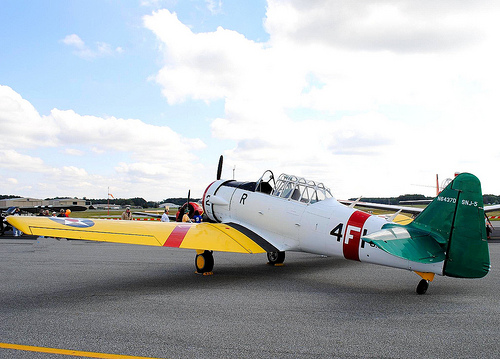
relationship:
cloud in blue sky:
[0, 0, 496, 194] [0, 2, 212, 140]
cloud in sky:
[0, 0, 496, 194] [2, 2, 481, 173]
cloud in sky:
[0, 0, 496, 194] [0, 0, 499, 207]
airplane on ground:
[4, 154, 491, 295] [0, 233, 498, 356]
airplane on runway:
[4, 154, 491, 295] [0, 233, 500, 355]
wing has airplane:
[4, 214, 276, 254] [4, 154, 491, 295]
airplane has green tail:
[4, 154, 491, 295] [341, 164, 492, 308]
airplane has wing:
[4, 154, 491, 295] [4, 214, 275, 256]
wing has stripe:
[4, 214, 275, 256] [160, 217, 199, 247]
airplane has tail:
[4, 154, 491, 295] [359, 170, 494, 287]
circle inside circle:
[50, 215, 98, 229] [49, 209, 95, 227]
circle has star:
[50, 215, 98, 229] [53, 216, 90, 227]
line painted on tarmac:
[0, 342, 154, 357] [0, 232, 499, 355]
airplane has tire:
[4, 154, 491, 295] [196, 242, 217, 277]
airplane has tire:
[4, 154, 491, 295] [412, 276, 430, 293]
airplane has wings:
[4, 154, 491, 295] [2, 214, 297, 260]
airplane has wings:
[4, 154, 491, 295] [355, 227, 447, 264]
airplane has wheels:
[4, 154, 491, 295] [195, 249, 284, 271]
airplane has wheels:
[4, 154, 491, 295] [402, 270, 444, 302]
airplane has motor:
[4, 154, 491, 295] [155, 157, 236, 218]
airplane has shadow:
[4, 154, 491, 295] [43, 270, 207, 300]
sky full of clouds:
[0, 0, 499, 207] [114, 35, 389, 108]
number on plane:
[332, 221, 344, 245] [44, 80, 497, 326]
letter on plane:
[342, 221, 362, 250] [44, 80, 497, 326]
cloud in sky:
[151, 0, 497, 112] [0, 0, 499, 207]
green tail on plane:
[359, 171, 493, 279] [53, 58, 499, 356]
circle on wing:
[47, 217, 95, 228] [12, 206, 279, 252]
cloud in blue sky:
[0, 0, 496, 194] [19, 24, 154, 110]